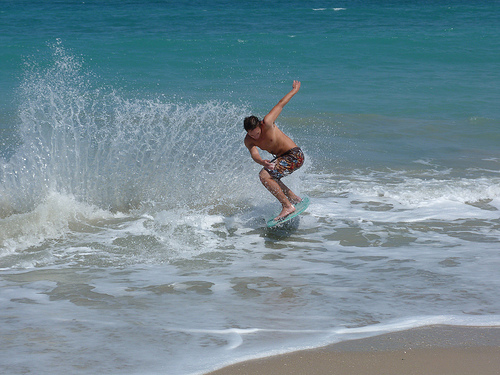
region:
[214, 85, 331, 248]
a man surfing in the ocean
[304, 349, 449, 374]
wet brown beach sand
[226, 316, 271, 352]
white seafoam on the water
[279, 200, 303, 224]
a wooden green surfboard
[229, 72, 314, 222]
a person extending an arm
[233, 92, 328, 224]
a person wearing colorful trunks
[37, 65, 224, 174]
salt water spraying into the air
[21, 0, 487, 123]
beautiful blue water in the ocean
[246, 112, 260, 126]
wet brown hair on a head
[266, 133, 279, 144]
a nipple on a chest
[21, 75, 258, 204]
White foamy ocean spray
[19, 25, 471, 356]
Surfboarding riding ocean waves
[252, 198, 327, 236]
Blue surfboard on waves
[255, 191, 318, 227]
Two feet planted on surfboard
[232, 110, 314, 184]
Man wearing multicolored trunks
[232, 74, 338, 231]
Man using arms for balance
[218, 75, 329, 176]
Left arm raised behind back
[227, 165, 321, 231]
Knees crouched on surfboard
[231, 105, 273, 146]
Man with brunette hair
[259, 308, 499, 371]
Tan smooth ocean beach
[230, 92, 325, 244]
male surfer in ocean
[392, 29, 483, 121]
white clouds in blue sky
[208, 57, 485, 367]
surfer tilted on shallow water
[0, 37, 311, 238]
lacy wall of water to surfer's side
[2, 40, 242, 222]
sheer wave fanning up and out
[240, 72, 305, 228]
surfer bent forward on blue board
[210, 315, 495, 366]
edge of water on tan sand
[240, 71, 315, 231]
arm extended in back of surfer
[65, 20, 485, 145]
turquoise water above gray water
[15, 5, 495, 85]
turquoise water below blue water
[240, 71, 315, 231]
surfer wearing blue and brown swim trunks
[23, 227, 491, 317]
white foam over water surface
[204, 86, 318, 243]
young man surfing in ocean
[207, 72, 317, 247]
young man surfing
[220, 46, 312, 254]
man surfing in ocean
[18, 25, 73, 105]
white and blue ocean waves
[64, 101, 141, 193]
white and blue ocean waves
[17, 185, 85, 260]
white and blue ocean waves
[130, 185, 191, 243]
white and blue ocean waves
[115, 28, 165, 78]
white and blue ocean waves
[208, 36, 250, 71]
white and blue ocean waves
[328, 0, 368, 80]
white and blue ocean waves